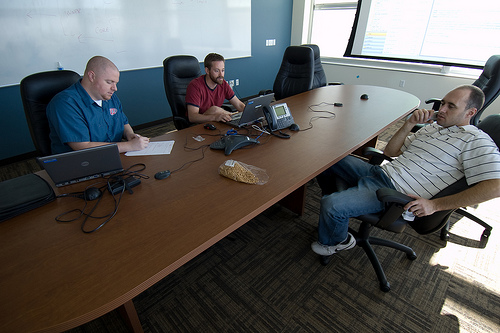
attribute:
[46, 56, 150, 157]
person — sitting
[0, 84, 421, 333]
table — large, brown, smooth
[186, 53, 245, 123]
person — sitting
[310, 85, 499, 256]
person — sitting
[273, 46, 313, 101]
chair — black, leather, empty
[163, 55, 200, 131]
chair — black, leather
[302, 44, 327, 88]
chair — black, leather, empty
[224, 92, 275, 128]
laptop — grey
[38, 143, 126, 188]
laptop — grey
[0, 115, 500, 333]
floor — black, brown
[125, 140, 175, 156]
paper — white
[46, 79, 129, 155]
shirt — dark blue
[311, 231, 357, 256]
sneaker — white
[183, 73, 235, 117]
shirt — red